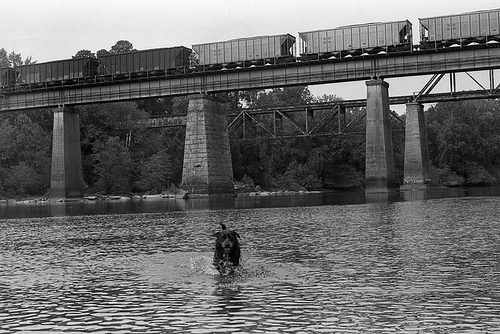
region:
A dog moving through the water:
[210, 221, 244, 280]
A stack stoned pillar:
[178, 91, 239, 200]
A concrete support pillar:
[361, 79, 401, 198]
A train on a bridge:
[0, 7, 499, 95]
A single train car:
[414, 5, 499, 54]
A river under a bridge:
[1, 182, 498, 331]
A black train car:
[93, 44, 193, 85]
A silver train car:
[185, 32, 297, 74]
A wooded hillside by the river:
[0, 36, 498, 196]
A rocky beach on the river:
[0, 187, 321, 208]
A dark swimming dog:
[211, 223, 243, 270]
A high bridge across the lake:
[0, 42, 497, 195]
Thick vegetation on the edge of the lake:
[0, 38, 497, 189]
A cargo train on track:
[0, 4, 499, 94]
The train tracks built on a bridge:
[2, 42, 498, 92]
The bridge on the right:
[106, 70, 498, 186]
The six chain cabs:
[0, 8, 498, 85]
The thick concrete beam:
[180, 95, 244, 194]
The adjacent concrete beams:
[364, 78, 431, 193]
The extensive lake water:
[0, 184, 498, 332]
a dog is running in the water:
[209, 220, 243, 269]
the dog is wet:
[211, 221, 243, 273]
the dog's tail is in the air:
[217, 217, 225, 230]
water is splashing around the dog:
[144, 247, 286, 288]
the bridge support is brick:
[179, 90, 229, 199]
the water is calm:
[3, 180, 495, 217]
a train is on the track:
[0, 8, 498, 91]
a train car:
[188, 31, 295, 71]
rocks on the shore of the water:
[6, 187, 322, 204]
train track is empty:
[131, 80, 499, 126]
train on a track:
[415, 13, 496, 39]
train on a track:
[296, 25, 417, 55]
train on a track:
[188, 31, 298, 66]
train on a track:
[97, 36, 189, 72]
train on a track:
[11, 56, 91, 87]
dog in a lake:
[200, 225, 272, 275]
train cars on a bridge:
[10, 0, 496, 93]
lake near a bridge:
[347, 202, 480, 313]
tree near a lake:
[105, 136, 167, 196]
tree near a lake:
[263, 151, 310, 188]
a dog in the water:
[200, 210, 257, 290]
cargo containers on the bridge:
[22, 22, 447, 81]